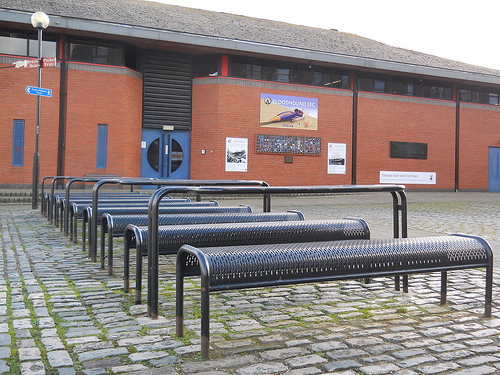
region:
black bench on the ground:
[167, 237, 494, 342]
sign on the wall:
[251, 92, 336, 133]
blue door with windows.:
[138, 116, 201, 185]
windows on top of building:
[356, 71, 493, 111]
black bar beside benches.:
[140, 181, 422, 311]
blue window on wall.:
[80, 107, 115, 174]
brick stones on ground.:
[11, 210, 107, 360]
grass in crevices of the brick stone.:
[30, 280, 76, 360]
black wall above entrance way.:
[135, 55, 196, 130]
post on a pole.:
[16, 55, 56, 75]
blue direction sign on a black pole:
[25, 81, 57, 96]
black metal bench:
[163, 226, 499, 353]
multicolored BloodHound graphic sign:
[259, 92, 323, 132]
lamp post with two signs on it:
[8, 6, 58, 218]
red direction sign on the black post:
[7, 53, 72, 74]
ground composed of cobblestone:
[2, 259, 96, 374]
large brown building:
[57, 2, 499, 176]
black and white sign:
[225, 136, 247, 171]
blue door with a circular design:
[141, 129, 191, 179]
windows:
[241, 64, 356, 86]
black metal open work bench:
[172, 220, 499, 352]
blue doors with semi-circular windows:
[131, 133, 200, 193]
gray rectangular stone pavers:
[228, 311, 415, 369]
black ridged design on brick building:
[128, 67, 197, 129]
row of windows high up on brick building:
[210, 52, 495, 119]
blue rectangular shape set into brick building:
[6, 106, 31, 183]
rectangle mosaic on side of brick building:
[249, 126, 329, 167]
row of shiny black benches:
[29, 160, 496, 347]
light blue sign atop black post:
[6, 71, 61, 212]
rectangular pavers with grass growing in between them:
[5, 262, 92, 374]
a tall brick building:
[1, 53, 483, 232]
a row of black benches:
[4, 175, 478, 309]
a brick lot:
[1, 180, 374, 372]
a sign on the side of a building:
[241, 77, 339, 126]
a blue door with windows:
[135, 110, 204, 191]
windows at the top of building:
[214, 50, 498, 118]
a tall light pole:
[1, 2, 54, 214]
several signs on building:
[185, 102, 357, 191]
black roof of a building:
[22, 1, 424, 75]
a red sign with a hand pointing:
[0, 45, 59, 72]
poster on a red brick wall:
[242, 80, 337, 138]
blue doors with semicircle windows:
[119, 114, 206, 193]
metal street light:
[18, 2, 57, 214]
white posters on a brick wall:
[214, 122, 355, 184]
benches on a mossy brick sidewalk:
[30, 190, 499, 350]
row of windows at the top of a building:
[195, 43, 499, 123]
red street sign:
[6, 52, 63, 72]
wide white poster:
[375, 163, 449, 197]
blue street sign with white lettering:
[21, 82, 66, 104]